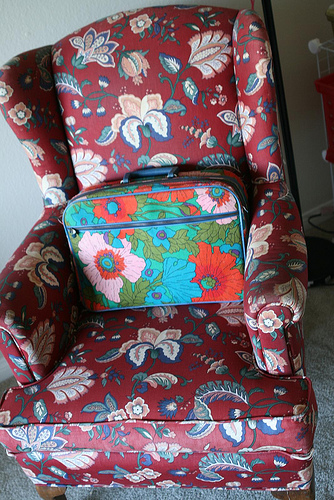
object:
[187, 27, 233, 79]
flower design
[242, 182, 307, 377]
arm rest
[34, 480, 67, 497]
left leg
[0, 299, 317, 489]
cushion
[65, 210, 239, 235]
zipper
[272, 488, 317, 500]
leg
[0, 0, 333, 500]
chair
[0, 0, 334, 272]
wall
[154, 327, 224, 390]
flower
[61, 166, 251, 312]
bag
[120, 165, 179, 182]
handle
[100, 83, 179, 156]
flower